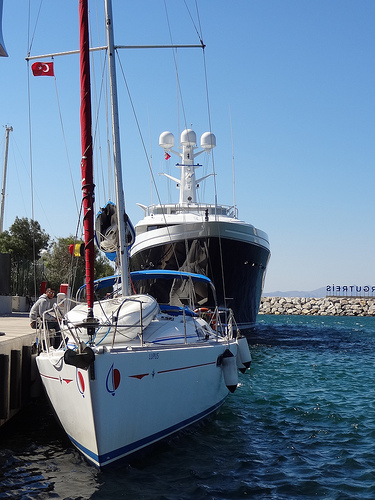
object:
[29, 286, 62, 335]
man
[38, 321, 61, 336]
pants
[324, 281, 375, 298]
sign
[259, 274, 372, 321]
background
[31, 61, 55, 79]
flag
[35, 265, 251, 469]
boat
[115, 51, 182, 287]
line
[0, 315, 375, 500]
water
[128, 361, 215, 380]
stripe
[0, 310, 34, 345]
surface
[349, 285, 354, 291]
letters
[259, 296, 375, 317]
wall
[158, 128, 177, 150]
antennas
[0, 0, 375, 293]
skies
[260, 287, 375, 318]
shore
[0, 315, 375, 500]
sea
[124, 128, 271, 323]
boat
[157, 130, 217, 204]
radar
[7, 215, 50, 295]
trees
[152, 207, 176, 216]
window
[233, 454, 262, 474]
waves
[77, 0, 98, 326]
mast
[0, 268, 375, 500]
harbor